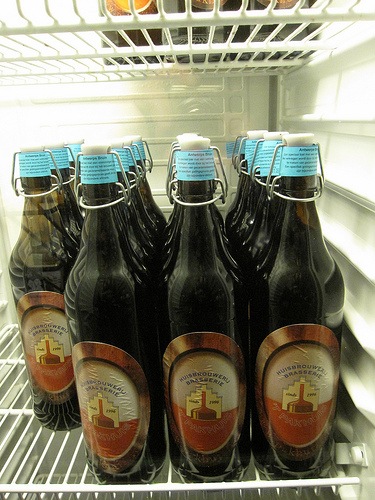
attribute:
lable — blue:
[252, 134, 328, 185]